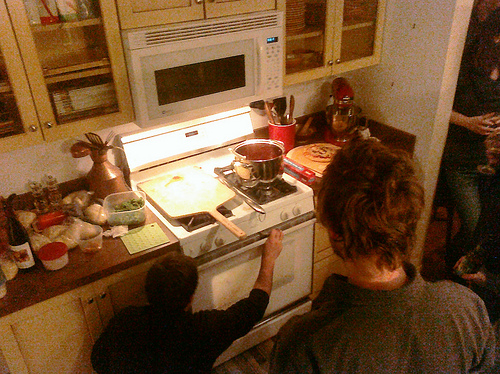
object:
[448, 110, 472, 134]
arm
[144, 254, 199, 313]
head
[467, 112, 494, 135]
hand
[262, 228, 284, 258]
hand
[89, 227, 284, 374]
person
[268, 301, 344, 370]
shoulder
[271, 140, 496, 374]
person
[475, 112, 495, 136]
fingers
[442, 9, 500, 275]
person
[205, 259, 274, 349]
arm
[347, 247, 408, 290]
neck